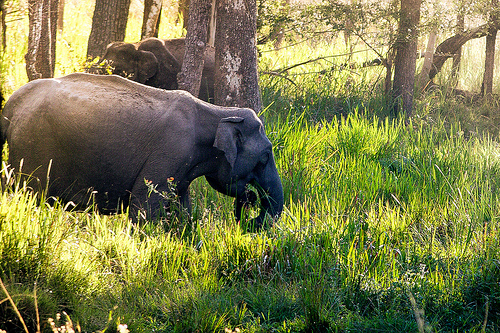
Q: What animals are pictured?
A: Elephants.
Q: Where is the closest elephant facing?
A: Right.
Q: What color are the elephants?
A: Grey.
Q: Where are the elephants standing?
A: In grass.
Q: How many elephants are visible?
A: 2.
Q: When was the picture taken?
A: During the day.